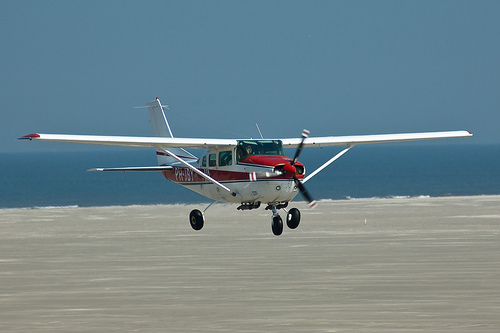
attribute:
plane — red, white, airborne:
[17, 96, 473, 236]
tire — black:
[271, 214, 283, 236]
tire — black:
[284, 205, 302, 229]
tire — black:
[188, 206, 204, 230]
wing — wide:
[15, 128, 475, 151]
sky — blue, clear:
[1, 1, 498, 205]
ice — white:
[2, 194, 498, 331]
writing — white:
[172, 166, 198, 181]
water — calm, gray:
[1, 140, 498, 208]